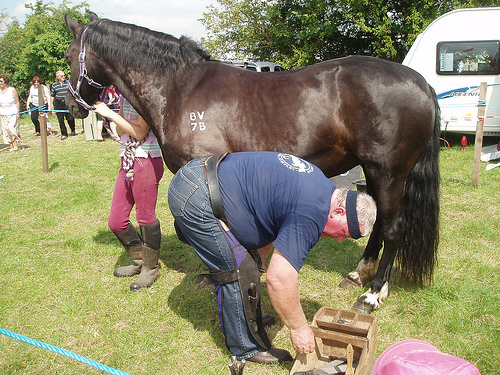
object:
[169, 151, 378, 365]
man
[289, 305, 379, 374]
box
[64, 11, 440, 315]
horse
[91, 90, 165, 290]
girl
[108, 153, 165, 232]
pants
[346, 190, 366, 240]
sweatband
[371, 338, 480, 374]
bag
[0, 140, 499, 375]
grass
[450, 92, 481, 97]
rope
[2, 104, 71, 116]
rope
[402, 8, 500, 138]
trailer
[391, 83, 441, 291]
tail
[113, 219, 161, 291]
boot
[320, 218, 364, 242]
sunburn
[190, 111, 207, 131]
letters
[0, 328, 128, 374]
hose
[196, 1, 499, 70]
tree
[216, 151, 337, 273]
t-shirt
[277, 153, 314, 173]
logo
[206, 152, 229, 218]
belt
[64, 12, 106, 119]
rein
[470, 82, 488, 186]
post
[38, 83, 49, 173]
post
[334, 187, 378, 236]
hair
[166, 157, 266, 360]
jeans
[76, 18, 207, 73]
hair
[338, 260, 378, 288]
right foot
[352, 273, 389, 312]
left foot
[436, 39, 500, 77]
window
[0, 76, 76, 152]
people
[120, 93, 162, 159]
shirt